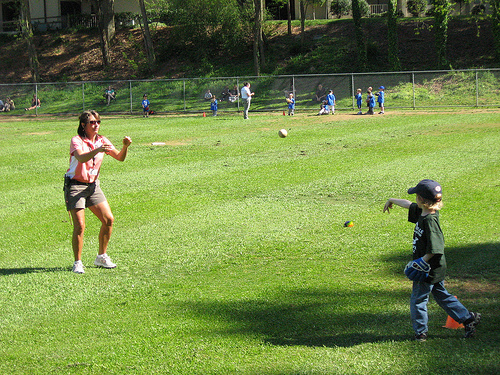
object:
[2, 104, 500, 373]
field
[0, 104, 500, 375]
grass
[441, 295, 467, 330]
cone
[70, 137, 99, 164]
arm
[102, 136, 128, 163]
arm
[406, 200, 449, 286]
t-shirt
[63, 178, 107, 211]
shorts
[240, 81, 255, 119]
woman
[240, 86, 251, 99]
top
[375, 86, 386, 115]
child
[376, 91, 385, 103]
shirt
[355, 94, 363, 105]
shirt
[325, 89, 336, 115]
child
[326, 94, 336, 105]
shirt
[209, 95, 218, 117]
child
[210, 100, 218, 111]
shirt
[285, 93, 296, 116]
child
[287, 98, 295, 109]
shirt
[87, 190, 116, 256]
leg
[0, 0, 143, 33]
homes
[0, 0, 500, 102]
hill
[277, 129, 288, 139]
ball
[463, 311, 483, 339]
shoe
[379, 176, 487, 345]
boy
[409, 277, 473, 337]
jeans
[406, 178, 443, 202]
cap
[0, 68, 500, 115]
fence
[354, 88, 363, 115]
kid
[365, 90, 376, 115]
child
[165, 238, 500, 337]
shade.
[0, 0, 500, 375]
park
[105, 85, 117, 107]
woman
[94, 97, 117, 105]
chair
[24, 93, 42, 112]
people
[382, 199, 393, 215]
hand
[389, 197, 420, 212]
extended arm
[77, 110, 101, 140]
hair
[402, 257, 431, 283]
baseball glove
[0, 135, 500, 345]
stripes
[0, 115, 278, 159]
stripes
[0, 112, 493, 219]
stripes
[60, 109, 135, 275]
woman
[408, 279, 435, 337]
legs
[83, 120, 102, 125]
sunglasses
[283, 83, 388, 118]
group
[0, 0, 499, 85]
air